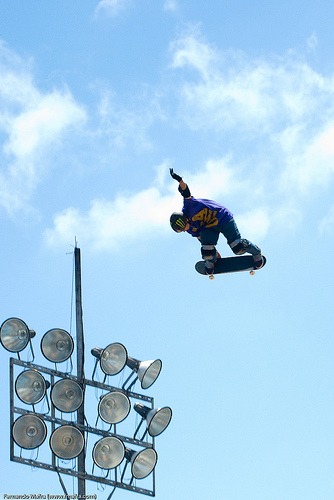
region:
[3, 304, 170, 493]
rows of lights angled in different directions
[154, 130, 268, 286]
skateboarder in the air performing trick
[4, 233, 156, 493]
wires connecting every light and the pole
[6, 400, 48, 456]
bulb in center of light fixture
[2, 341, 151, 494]
rectangular metal support for lights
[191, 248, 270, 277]
wheels showing below skateboard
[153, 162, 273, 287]
skateboarder against fluffy white clouds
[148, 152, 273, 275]
skateboarder's arm reaching toward the sky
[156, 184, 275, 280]
skateboarder wearing blue and yellow outfit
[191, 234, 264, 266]
black and grey knee pads covering joints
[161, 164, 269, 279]
the skater is in mid air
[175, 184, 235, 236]
the skater is wearing a blue shirt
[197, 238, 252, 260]
the skater is wearing knee pads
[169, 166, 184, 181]
the skater is wearing gloves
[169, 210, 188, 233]
the skater is wearing a helmet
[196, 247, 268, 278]
the skater is holding the skateboard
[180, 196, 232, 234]
the skater's shirt has yellow writing on it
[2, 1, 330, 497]
the sky is deep blue in color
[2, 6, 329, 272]
clouds are high in the sky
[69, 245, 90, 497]
a long pole holds many lights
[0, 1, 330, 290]
blue sky with wispy clouds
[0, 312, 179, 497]
panel of spot lights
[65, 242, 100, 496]
tall grey metal post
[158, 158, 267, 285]
skateboarder wearing a striped helmet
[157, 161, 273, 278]
skateboarder in blue and yellow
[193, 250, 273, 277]
blue and yellow skateboard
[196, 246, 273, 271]
black and white shoes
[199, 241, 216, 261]
black and silver kneepad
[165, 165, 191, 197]
black glove and armband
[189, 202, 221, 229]
yellow design on blue shirt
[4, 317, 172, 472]
There are twelve lights on a pole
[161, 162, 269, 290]
A guy on a skateboard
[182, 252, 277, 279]
The bottom of the skateboard is black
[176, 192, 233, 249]
The guy has a blue shirt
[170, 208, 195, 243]
The guy is wearing a black monster helmet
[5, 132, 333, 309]
The man is in the sky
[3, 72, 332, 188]
The sky is clear but a few clouds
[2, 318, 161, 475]
The lights are big and round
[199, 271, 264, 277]
The wheels of the skateboard are red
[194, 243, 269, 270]
The skateboarder is wearing black knee pads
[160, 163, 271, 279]
skater is in air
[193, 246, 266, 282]
skater is on skateboard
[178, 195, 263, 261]
skater wearing blue outfit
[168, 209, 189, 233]
skater wearing helmet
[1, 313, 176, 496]
lights on light pole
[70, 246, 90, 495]
light pole holds lights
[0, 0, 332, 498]
sky is very clear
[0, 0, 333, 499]
sky has few clouds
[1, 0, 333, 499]
sky is light blue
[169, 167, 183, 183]
glove on skater's left hand